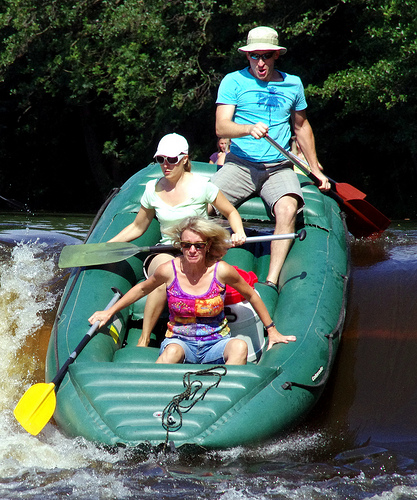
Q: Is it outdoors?
A: Yes, it is outdoors.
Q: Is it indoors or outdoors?
A: It is outdoors.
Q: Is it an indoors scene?
A: No, it is outdoors.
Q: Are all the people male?
A: No, they are both male and female.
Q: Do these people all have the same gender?
A: No, they are both male and female.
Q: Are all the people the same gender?
A: No, they are both male and female.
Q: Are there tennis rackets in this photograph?
A: No, there are no tennis rackets.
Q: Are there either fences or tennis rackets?
A: No, there are no tennis rackets or fences.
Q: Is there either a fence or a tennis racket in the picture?
A: No, there are no rackets or fences.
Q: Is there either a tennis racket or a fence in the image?
A: No, there are no rackets or fences.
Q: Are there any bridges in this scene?
A: No, there are no bridges.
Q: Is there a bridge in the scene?
A: No, there are no bridges.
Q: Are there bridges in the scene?
A: No, there are no bridges.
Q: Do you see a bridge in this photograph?
A: No, there are no bridges.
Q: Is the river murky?
A: Yes, the river is murky.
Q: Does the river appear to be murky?
A: Yes, the river is murky.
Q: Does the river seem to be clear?
A: No, the river is murky.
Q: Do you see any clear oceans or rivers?
A: No, there is a river but it is murky.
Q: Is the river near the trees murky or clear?
A: The river is murky.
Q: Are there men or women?
A: Yes, there is a woman.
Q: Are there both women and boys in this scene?
A: No, there is a woman but no boys.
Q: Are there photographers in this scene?
A: No, there are no photographers.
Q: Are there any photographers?
A: No, there are no photographers.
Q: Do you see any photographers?
A: No, there are no photographers.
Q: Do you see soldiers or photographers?
A: No, there are no photographers or soldiers.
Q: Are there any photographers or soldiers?
A: No, there are no photographers or soldiers.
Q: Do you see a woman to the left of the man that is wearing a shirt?
A: Yes, there is a woman to the left of the man.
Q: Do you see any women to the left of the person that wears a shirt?
A: Yes, there is a woman to the left of the man.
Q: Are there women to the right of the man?
A: No, the woman is to the left of the man.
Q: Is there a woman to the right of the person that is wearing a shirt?
A: No, the woman is to the left of the man.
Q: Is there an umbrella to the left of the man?
A: No, there is a woman to the left of the man.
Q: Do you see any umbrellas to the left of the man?
A: No, there is a woman to the left of the man.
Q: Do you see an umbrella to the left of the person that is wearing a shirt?
A: No, there is a woman to the left of the man.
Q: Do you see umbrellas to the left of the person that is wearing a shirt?
A: No, there is a woman to the left of the man.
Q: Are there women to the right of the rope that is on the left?
A: Yes, there is a woman to the right of the rope.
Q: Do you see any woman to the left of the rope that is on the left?
A: No, the woman is to the right of the rope.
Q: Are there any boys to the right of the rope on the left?
A: No, there is a woman to the right of the rope.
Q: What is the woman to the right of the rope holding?
A: The woman is holding the paddle.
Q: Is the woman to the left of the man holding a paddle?
A: Yes, the woman is holding a paddle.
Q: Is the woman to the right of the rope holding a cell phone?
A: No, the woman is holding a paddle.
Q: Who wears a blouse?
A: The woman wears a blouse.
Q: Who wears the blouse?
A: The woman wears a blouse.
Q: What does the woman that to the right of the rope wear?
A: The woman wears a blouse.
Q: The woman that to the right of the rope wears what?
A: The woman wears a blouse.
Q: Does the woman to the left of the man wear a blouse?
A: Yes, the woman wears a blouse.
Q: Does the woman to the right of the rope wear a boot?
A: No, the woman wears a blouse.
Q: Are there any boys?
A: No, there are no boys.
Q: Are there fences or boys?
A: No, there are no boys or fences.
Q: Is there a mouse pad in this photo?
A: No, there are no mouse pads.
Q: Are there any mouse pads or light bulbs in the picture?
A: No, there are no mouse pads or light bulbs.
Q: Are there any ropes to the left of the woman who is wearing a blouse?
A: Yes, there is a rope to the left of the woman.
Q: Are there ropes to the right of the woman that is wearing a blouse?
A: No, the rope is to the left of the woman.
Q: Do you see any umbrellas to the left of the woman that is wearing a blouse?
A: No, there is a rope to the left of the woman.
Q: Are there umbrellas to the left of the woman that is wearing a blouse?
A: No, there is a rope to the left of the woman.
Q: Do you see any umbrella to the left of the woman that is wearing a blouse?
A: No, there is a rope to the left of the woman.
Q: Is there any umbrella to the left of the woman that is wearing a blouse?
A: No, there is a rope to the left of the woman.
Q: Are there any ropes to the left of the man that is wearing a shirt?
A: Yes, there is a rope to the left of the man.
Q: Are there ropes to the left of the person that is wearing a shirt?
A: Yes, there is a rope to the left of the man.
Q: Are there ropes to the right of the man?
A: No, the rope is to the left of the man.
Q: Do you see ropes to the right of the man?
A: No, the rope is to the left of the man.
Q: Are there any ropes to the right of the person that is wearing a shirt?
A: No, the rope is to the left of the man.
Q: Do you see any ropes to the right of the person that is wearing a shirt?
A: No, the rope is to the left of the man.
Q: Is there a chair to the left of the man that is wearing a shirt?
A: No, there is a rope to the left of the man.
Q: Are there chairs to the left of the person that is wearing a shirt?
A: No, there is a rope to the left of the man.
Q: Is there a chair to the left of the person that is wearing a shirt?
A: No, there is a rope to the left of the man.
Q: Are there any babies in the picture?
A: No, there are no babies.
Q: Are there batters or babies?
A: No, there are no babies or batters.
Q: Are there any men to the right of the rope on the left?
A: Yes, there is a man to the right of the rope.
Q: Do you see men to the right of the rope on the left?
A: Yes, there is a man to the right of the rope.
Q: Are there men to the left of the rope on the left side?
A: No, the man is to the right of the rope.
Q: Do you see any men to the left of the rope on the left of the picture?
A: No, the man is to the right of the rope.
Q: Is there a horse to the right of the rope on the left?
A: No, there is a man to the right of the rope.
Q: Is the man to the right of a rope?
A: Yes, the man is to the right of a rope.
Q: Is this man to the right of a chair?
A: No, the man is to the right of a rope.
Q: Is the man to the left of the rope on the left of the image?
A: No, the man is to the right of the rope.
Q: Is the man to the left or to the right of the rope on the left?
A: The man is to the right of the rope.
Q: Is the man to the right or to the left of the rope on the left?
A: The man is to the right of the rope.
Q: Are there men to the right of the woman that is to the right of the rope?
A: Yes, there is a man to the right of the woman.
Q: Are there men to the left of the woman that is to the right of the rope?
A: No, the man is to the right of the woman.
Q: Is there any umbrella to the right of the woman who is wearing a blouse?
A: No, there is a man to the right of the woman.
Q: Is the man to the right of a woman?
A: Yes, the man is to the right of a woman.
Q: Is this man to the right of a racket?
A: No, the man is to the right of a woman.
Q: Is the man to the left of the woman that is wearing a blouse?
A: No, the man is to the right of the woman.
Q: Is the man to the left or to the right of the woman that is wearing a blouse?
A: The man is to the right of the woman.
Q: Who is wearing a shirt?
A: The man is wearing a shirt.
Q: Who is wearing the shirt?
A: The man is wearing a shirt.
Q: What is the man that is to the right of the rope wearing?
A: The man is wearing a shirt.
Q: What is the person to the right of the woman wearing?
A: The man is wearing a shirt.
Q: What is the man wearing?
A: The man is wearing a shirt.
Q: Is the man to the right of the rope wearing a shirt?
A: Yes, the man is wearing a shirt.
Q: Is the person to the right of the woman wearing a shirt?
A: Yes, the man is wearing a shirt.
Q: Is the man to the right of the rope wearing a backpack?
A: No, the man is wearing a shirt.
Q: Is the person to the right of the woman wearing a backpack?
A: No, the man is wearing a shirt.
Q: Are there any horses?
A: No, there are no horses.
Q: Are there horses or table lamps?
A: No, there are no horses or table lamps.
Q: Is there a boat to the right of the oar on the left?
A: No, there is a rope to the right of the paddle.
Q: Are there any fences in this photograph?
A: No, there are no fences.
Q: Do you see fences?
A: No, there are no fences.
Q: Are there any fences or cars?
A: No, there are no fences or cars.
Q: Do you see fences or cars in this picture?
A: No, there are no fences or cars.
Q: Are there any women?
A: Yes, there is a woman.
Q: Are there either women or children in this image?
A: Yes, there is a woman.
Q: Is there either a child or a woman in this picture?
A: Yes, there is a woman.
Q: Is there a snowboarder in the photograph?
A: No, there are no snowboarders.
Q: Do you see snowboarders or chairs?
A: No, there are no snowboarders or chairs.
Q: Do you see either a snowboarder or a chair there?
A: No, there are no snowboarders or chairs.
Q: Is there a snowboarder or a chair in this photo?
A: No, there are no snowboarders or chairs.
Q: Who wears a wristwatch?
A: The woman wears a wristwatch.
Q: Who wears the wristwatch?
A: The woman wears a wristwatch.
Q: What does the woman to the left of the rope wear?
A: The woman wears a wristwatch.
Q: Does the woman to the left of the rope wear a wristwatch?
A: Yes, the woman wears a wristwatch.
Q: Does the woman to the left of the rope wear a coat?
A: No, the woman wears a wristwatch.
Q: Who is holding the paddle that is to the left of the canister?
A: The woman is holding the oar.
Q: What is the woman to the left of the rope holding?
A: The woman is holding the paddle.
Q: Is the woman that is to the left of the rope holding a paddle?
A: Yes, the woman is holding a paddle.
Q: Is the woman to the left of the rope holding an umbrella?
A: No, the woman is holding a paddle.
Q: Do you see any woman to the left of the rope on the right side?
A: Yes, there is a woman to the left of the rope.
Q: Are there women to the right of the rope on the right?
A: No, the woman is to the left of the rope.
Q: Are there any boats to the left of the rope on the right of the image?
A: No, there is a woman to the left of the rope.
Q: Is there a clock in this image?
A: No, there are no clocks.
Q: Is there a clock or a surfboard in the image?
A: No, there are no clocks or surfboards.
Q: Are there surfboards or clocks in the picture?
A: No, there are no clocks or surfboards.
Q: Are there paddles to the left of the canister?
A: Yes, there is a paddle to the left of the canister.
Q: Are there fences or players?
A: No, there are no fences or players.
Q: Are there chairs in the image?
A: No, there are no chairs.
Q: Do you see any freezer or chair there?
A: No, there are no chairs or refrigerators.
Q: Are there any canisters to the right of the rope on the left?
A: Yes, there is a canister to the right of the rope.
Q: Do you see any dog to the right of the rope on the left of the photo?
A: No, there is a canister to the right of the rope.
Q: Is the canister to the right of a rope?
A: Yes, the canister is to the right of a rope.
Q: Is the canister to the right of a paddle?
A: Yes, the canister is to the right of a paddle.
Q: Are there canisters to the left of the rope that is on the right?
A: Yes, there is a canister to the left of the rope.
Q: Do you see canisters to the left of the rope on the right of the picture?
A: Yes, there is a canister to the left of the rope.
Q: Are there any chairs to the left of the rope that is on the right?
A: No, there is a canister to the left of the rope.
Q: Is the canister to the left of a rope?
A: Yes, the canister is to the left of a rope.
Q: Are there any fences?
A: No, there are no fences.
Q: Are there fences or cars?
A: No, there are no fences or cars.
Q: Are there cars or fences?
A: No, there are no fences or cars.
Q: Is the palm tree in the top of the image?
A: Yes, the palm tree is in the top of the image.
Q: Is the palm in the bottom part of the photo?
A: No, the palm is in the top of the image.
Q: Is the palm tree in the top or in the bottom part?
A: The palm tree is in the top of the image.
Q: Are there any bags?
A: No, there are no bags.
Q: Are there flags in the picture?
A: No, there are no flags.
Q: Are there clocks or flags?
A: No, there are no flags or clocks.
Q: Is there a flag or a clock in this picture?
A: No, there are no flags or clocks.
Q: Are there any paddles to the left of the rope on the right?
A: Yes, there is a paddle to the left of the rope.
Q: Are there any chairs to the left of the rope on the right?
A: No, there is a paddle to the left of the rope.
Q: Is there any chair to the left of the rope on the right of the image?
A: No, there is a paddle to the left of the rope.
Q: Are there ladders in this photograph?
A: No, there are no ladders.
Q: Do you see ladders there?
A: No, there are no ladders.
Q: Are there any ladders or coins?
A: No, there are no ladders or coins.